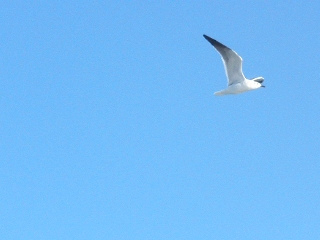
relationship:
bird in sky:
[202, 34, 267, 98] [1, 2, 317, 236]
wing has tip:
[202, 33, 247, 86] [202, 34, 233, 52]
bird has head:
[202, 34, 267, 98] [255, 82, 270, 91]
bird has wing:
[202, 34, 267, 98] [202, 33, 247, 86]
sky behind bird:
[1, 2, 317, 236] [202, 34, 267, 98]